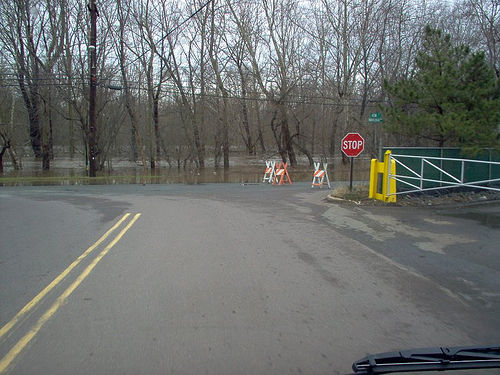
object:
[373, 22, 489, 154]
tree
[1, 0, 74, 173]
tree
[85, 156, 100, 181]
woods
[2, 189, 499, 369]
street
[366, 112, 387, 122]
sign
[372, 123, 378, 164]
pole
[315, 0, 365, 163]
tree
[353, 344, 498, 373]
wiper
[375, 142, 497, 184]
fence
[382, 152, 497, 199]
gate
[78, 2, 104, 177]
pole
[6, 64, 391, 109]
power lines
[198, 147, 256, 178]
field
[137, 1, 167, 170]
tree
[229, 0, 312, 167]
tree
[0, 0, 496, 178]
field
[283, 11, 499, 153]
tree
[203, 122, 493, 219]
fence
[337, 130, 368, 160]
sign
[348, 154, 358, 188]
pole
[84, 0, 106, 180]
trees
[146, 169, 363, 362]
road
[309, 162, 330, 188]
barrier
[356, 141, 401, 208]
barrier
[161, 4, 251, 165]
tree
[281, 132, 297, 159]
woods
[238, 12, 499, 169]
field